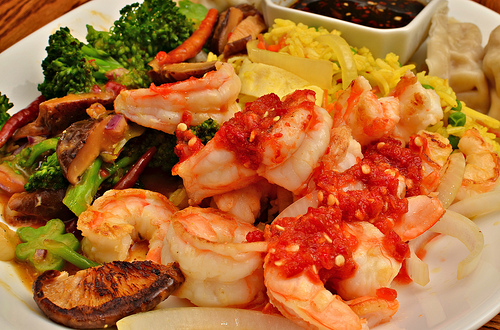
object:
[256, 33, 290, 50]
carrot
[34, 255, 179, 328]
wedge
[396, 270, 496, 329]
plate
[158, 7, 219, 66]
carrot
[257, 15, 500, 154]
fried rice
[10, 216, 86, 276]
vegetable piece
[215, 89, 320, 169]
marinara sauce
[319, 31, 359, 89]
onion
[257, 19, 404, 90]
rice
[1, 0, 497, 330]
bowl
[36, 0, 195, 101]
sauted broccoli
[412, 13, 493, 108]
wontons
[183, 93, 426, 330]
shrimp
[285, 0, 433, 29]
sauce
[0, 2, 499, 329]
dish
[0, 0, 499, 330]
meal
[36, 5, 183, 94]
broccoli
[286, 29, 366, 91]
brown building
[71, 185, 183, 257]
meat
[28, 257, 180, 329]
mushroom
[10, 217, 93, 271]
green vegetable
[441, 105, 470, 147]
pea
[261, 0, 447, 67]
bowl.